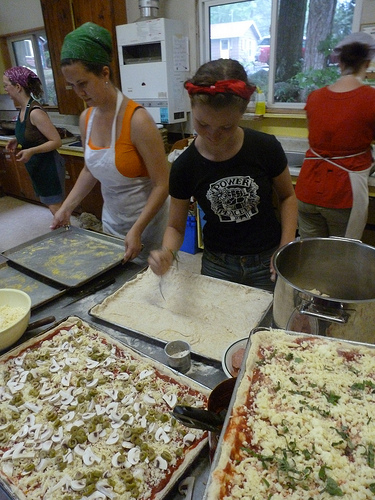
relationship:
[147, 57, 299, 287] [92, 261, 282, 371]
girl pokes dough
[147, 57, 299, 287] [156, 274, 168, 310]
girl has fork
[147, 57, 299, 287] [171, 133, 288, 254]
girl wears t-shirt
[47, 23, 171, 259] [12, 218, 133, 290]
woman prepares tray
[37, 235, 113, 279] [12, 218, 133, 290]
cornmeal on tray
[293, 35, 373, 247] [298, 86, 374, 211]
woman wears top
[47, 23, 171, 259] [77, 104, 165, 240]
woman wears apron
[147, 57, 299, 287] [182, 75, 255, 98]
girl wears headband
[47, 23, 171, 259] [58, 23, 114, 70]
woman wears scarf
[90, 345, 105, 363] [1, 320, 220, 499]
mushroom on pizza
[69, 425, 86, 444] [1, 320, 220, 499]
mushroom on pizza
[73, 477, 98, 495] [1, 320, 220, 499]
mushroom on pizza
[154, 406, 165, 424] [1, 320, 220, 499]
mushroom on pizza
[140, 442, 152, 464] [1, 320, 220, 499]
mushroom on pizza